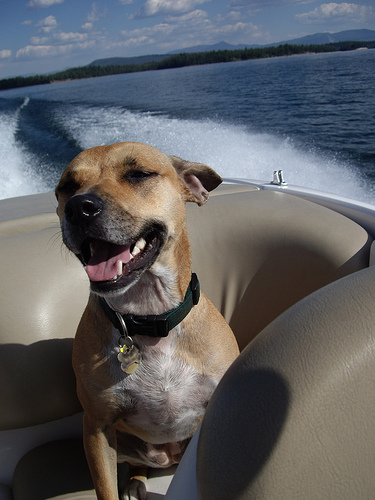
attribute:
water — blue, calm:
[1, 42, 375, 216]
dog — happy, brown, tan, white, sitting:
[42, 139, 226, 499]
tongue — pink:
[83, 237, 136, 288]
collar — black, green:
[92, 267, 204, 377]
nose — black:
[60, 192, 107, 230]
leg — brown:
[73, 414, 132, 499]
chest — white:
[97, 329, 221, 447]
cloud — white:
[17, 15, 61, 37]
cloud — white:
[76, 17, 97, 36]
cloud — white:
[160, 7, 211, 28]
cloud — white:
[284, 1, 374, 34]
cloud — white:
[108, 33, 158, 53]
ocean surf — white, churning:
[1, 97, 374, 233]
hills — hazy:
[165, 26, 373, 58]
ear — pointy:
[164, 148, 228, 213]